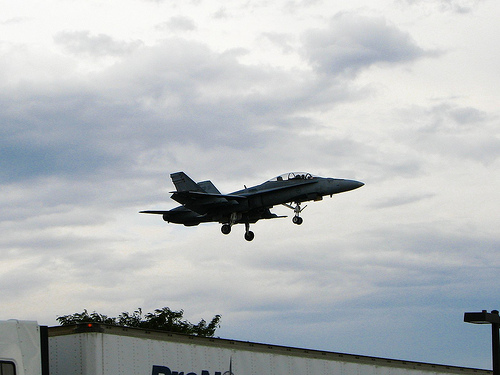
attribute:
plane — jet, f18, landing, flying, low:
[139, 170, 365, 241]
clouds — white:
[2, 1, 499, 373]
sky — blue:
[2, 0, 499, 368]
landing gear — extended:
[292, 201, 303, 225]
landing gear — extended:
[243, 221, 255, 239]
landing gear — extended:
[222, 214, 236, 234]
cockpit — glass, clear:
[271, 171, 313, 180]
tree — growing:
[58, 305, 220, 337]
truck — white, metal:
[1, 320, 499, 374]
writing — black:
[152, 365, 231, 374]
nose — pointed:
[315, 176, 365, 198]